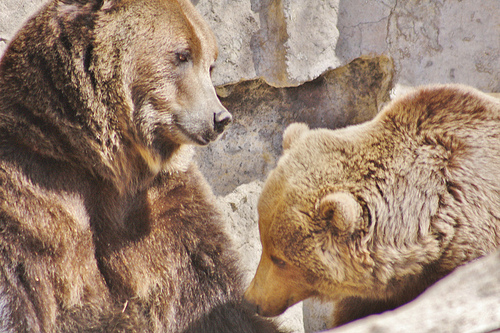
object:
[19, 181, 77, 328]
fur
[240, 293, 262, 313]
nose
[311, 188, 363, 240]
ear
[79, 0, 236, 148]
head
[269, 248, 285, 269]
eye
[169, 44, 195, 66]
eye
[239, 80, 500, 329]
bear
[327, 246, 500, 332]
rock face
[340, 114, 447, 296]
neck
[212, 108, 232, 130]
nose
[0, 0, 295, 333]
bear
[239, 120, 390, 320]
head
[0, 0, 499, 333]
zoo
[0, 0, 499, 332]
background